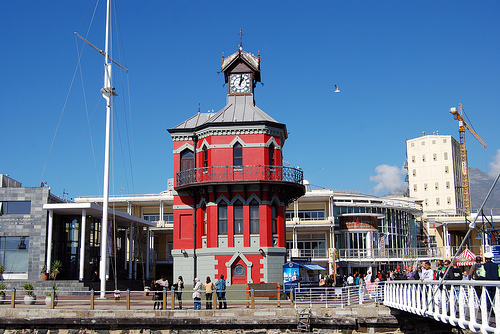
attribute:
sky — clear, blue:
[3, 2, 499, 217]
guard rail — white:
[383, 278, 500, 334]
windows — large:
[232, 139, 245, 168]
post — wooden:
[384, 280, 500, 332]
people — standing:
[389, 259, 498, 278]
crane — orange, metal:
[449, 102, 488, 215]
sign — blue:
[284, 265, 296, 284]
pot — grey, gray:
[46, 296, 58, 307]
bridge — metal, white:
[383, 280, 500, 333]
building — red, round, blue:
[165, 52, 305, 296]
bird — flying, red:
[333, 81, 340, 96]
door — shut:
[230, 258, 249, 283]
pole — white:
[75, 0, 131, 298]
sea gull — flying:
[333, 83, 341, 96]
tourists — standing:
[192, 278, 228, 310]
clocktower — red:
[170, 49, 306, 298]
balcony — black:
[174, 166, 304, 202]